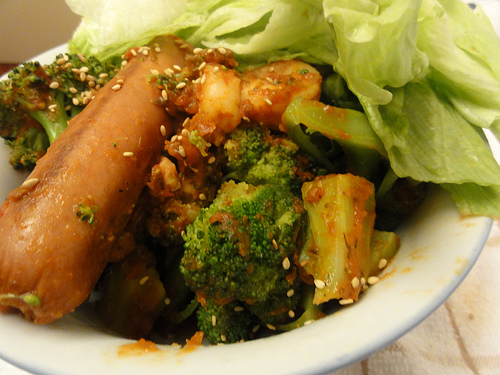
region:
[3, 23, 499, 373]
A round white bowl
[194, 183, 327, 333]
cooked broccoli with season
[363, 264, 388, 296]
Sesame seeds on a white bowl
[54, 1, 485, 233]
lettuce in a white bowl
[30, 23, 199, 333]
cooked meat in a white bowl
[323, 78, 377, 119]
sauce on broccoli and lettuce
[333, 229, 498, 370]
cloth under white bowl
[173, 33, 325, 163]
vegetable with sauce in a bowl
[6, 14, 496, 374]
a salad with meat and broccoli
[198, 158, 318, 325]
sauce seeds and broccoli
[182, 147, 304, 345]
broccoli in a bowl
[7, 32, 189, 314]
squash in a bowl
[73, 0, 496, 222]
light green cabbage in a bowl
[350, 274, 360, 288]
sesame seed on a piece of broccoli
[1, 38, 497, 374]
white bowl with a sesame seed vegetable entre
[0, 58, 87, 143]
a piece of broccoli with sauce on it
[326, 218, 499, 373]
white table cloth under the bowl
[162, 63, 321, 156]
piece of chicken with sauce on it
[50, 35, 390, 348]
sesame seeds on the entree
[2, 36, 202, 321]
long brown vegetable on the entree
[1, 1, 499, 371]
bowl with food on it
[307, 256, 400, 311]
small white seeds on the food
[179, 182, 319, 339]
hunk of green broccoli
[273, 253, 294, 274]
seed on the broccoli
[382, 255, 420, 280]
sauce stain on the bowl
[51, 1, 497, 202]
light green leafy lettuce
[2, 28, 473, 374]
shallow white bowl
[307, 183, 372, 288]
brown sauce on the green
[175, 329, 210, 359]
bit of food on the plate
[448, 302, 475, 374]
line in the table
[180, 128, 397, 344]
cooked bunch of broccoli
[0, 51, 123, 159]
a stem of broccoli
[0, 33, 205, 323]
a cooked orange carrot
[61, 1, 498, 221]
green iceberg lettuce leaf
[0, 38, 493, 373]
a white plate with cooked vegetables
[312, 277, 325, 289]
a white sesame seed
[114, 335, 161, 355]
a smear of orange sauce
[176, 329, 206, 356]
a bit of sauce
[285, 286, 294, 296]
a tiny sesame seed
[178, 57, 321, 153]
cooked potatoes with seeds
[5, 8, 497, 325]
Food in a bowl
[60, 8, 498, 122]
Lettuc on top of a bowl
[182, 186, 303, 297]
A piece of brocolli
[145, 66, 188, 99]
Sesame seeds on top of food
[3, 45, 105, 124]
Brocolli and sesame seeds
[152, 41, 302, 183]
Sauce on top of food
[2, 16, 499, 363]
Food in a white bowl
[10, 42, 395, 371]
a white bowl with food in it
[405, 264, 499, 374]
A table cloth under a bowl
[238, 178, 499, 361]
A bowl on top of a table cloth